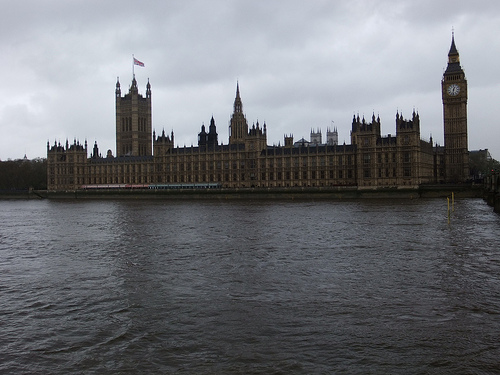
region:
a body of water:
[62, 211, 383, 360]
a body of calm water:
[221, 249, 405, 371]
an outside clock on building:
[426, 43, 499, 138]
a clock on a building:
[412, 56, 482, 174]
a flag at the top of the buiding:
[112, 52, 158, 87]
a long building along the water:
[37, 63, 486, 239]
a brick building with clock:
[425, 35, 489, 181]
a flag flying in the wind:
[112, 47, 175, 93]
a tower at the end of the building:
[434, 31, 478, 194]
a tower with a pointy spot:
[222, 71, 262, 151]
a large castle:
[38, 35, 470, 217]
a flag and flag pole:
[103, 44, 152, 119]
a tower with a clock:
[423, 60, 481, 118]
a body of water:
[71, 159, 476, 318]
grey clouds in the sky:
[238, 21, 422, 74]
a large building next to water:
[20, 84, 480, 240]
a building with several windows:
[45, 140, 418, 193]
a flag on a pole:
[119, 41, 156, 77]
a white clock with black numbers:
[421, 69, 473, 116]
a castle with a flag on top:
[32, 38, 476, 197]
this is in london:
[27, 26, 478, 208]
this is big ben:
[400, 21, 487, 147]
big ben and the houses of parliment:
[47, 48, 488, 190]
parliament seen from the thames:
[34, 30, 498, 288]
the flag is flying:
[29, 16, 188, 141]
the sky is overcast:
[202, 43, 375, 119]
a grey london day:
[46, 31, 493, 263]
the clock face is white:
[426, 71, 473, 113]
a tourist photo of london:
[94, 28, 494, 177]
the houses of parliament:
[67, 49, 399, 201]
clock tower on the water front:
[436, 26, 497, 184]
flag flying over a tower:
[97, 34, 179, 118]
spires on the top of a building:
[35, 124, 105, 161]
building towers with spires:
[300, 127, 353, 167]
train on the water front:
[37, 173, 229, 197]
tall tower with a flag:
[98, 37, 183, 184]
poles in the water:
[432, 180, 467, 250]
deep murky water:
[20, 208, 282, 330]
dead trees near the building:
[10, 161, 45, 193]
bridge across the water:
[467, 154, 497, 195]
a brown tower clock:
[435, 45, 479, 182]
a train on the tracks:
[75, 180, 237, 197]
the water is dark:
[111, 238, 387, 320]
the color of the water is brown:
[96, 241, 329, 332]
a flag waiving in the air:
[125, 50, 152, 78]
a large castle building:
[52, 33, 499, 218]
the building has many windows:
[55, 151, 407, 186]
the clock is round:
[439, 76, 472, 102]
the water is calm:
[61, 251, 393, 320]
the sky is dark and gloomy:
[176, 7, 364, 73]